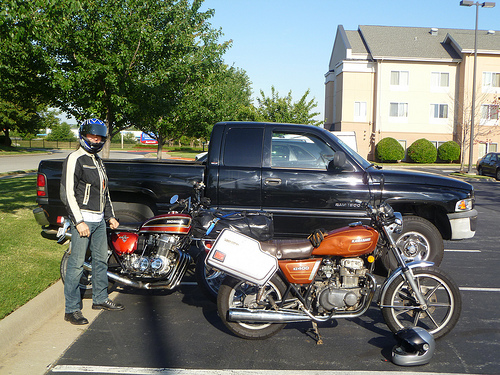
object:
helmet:
[77, 117, 109, 155]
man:
[58, 116, 127, 326]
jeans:
[63, 218, 109, 313]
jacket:
[59, 146, 116, 223]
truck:
[32, 120, 478, 275]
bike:
[204, 199, 462, 340]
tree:
[123, 33, 245, 159]